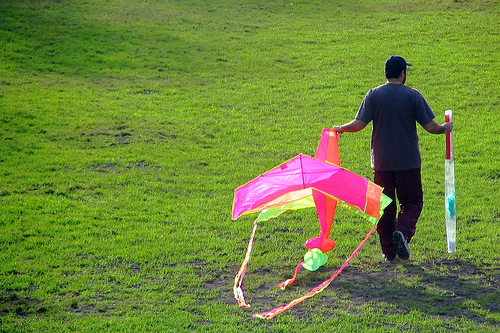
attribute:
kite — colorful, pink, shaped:
[228, 125, 395, 325]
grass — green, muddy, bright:
[1, 2, 499, 333]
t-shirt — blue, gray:
[355, 83, 436, 175]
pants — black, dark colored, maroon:
[370, 167, 425, 259]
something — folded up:
[441, 106, 459, 256]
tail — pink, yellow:
[230, 218, 260, 309]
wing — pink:
[230, 150, 386, 225]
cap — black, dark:
[384, 54, 414, 70]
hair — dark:
[384, 70, 406, 79]